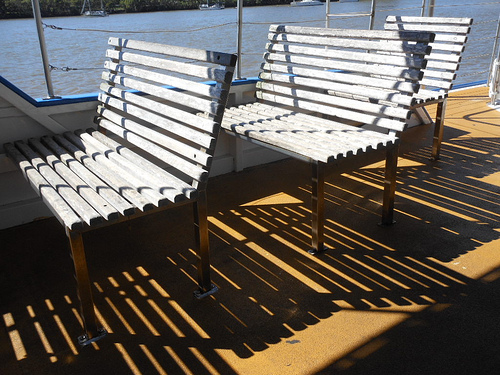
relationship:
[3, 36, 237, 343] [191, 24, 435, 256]
bench in front of a bench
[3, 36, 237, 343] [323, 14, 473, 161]
bench in front of a bench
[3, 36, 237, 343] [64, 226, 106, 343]
bench has a leg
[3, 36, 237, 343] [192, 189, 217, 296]
bench has a leg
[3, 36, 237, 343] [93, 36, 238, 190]
bench has a bench back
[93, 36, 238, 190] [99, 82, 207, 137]
bench back has a slat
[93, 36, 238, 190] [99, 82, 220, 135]
bench back has a slat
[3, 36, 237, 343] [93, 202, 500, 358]
bench casts a shadow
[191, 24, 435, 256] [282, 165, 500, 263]
bench casts a shadow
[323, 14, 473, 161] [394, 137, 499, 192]
bench casts a shadow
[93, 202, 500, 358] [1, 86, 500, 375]
shadow on deck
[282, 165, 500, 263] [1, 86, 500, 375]
shadow on deck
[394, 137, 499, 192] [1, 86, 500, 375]
shadow on deck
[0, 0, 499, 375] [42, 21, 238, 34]
boat has a safety wire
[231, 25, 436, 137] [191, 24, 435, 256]
shadow on a bench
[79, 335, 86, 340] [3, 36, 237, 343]
bolt holding down a bench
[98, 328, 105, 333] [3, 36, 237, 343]
bolt holding down a bench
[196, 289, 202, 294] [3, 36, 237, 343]
bolt holding down a bench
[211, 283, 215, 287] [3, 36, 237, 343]
bolt holding down a bench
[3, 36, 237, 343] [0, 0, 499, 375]
bench on boat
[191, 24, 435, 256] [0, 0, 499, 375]
bench on boat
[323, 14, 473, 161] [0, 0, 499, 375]
bench on boat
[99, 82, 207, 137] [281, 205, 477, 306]
slat casting a shadow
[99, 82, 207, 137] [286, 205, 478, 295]
slat casting a shadow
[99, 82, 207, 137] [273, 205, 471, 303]
slat casting a shadow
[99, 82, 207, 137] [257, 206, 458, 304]
slat casting a shadow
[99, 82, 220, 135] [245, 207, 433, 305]
slat casting a shadow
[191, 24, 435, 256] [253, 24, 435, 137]
bench has a bench back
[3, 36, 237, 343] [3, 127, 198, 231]
bench has a seat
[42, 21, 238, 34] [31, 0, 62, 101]
safety wire attached to a pole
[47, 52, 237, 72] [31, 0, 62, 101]
safety wire attached to a pole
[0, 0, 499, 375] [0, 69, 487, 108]
boat has an edge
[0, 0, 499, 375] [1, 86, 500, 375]
boat has a deck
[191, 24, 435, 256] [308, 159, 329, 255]
bench has a leg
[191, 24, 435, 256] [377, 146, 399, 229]
bench has a leg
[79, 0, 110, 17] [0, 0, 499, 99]
sailboat on side of body of water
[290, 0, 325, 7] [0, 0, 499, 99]
boat on body of water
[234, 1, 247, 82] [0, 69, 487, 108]
pole on edge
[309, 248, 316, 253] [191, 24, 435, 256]
bolt holds down a bench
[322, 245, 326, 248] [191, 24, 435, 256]
bolt holds down a bench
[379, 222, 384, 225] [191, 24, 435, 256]
bolt holds down a bench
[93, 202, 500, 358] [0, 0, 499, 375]
shadow on boat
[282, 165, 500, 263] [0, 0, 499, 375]
shadow on boat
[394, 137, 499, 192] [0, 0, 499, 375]
shadow on boat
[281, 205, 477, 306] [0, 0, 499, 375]
shadow on boat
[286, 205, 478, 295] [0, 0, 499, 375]
shadow on boat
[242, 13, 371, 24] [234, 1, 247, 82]
safety wire connected to a pole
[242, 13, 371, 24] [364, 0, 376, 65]
safety wire connected to a pole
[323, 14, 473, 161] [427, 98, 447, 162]
bench has a leg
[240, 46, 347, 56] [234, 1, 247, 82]
safety wire connected to a pole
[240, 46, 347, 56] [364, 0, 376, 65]
safety wire connected to a pole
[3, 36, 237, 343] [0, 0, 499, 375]
bench on a boat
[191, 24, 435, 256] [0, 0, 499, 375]
bench on a boat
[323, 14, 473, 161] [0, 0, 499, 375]
bench on a boat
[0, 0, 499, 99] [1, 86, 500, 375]
body of water next to deck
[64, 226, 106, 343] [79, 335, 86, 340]
leg fastened by a bolt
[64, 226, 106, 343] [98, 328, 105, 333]
leg fastened by a bolt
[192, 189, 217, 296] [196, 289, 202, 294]
leg fastened by a bolt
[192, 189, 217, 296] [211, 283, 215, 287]
leg fastened by a bolt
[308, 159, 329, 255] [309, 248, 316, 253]
leg fastened by a bolt